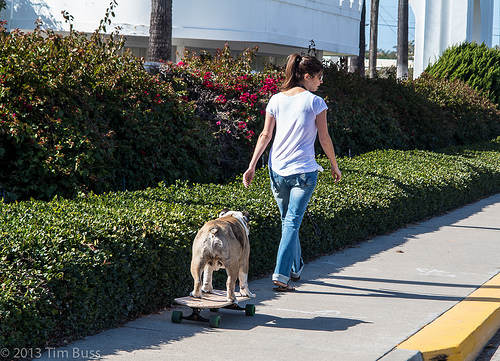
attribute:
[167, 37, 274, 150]
flowers — pink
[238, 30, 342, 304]
woman — wearing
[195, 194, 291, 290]
dog — riding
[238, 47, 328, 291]
woman — walking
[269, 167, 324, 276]
jeans — blue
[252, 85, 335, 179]
tee shirt — white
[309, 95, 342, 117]
sleeve — short sleeve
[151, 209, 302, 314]
wooden skateboard — brown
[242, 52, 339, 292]
woman — wearing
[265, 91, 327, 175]
shirt — white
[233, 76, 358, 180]
t-shirt. — white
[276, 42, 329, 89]
hair — brown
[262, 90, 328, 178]
shirt — short sleeved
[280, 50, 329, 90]
hair — dark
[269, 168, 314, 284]
jeans — blue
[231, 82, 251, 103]
flowers — pink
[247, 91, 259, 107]
flowers — pink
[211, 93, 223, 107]
flowers — pink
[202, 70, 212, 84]
flowers — pink